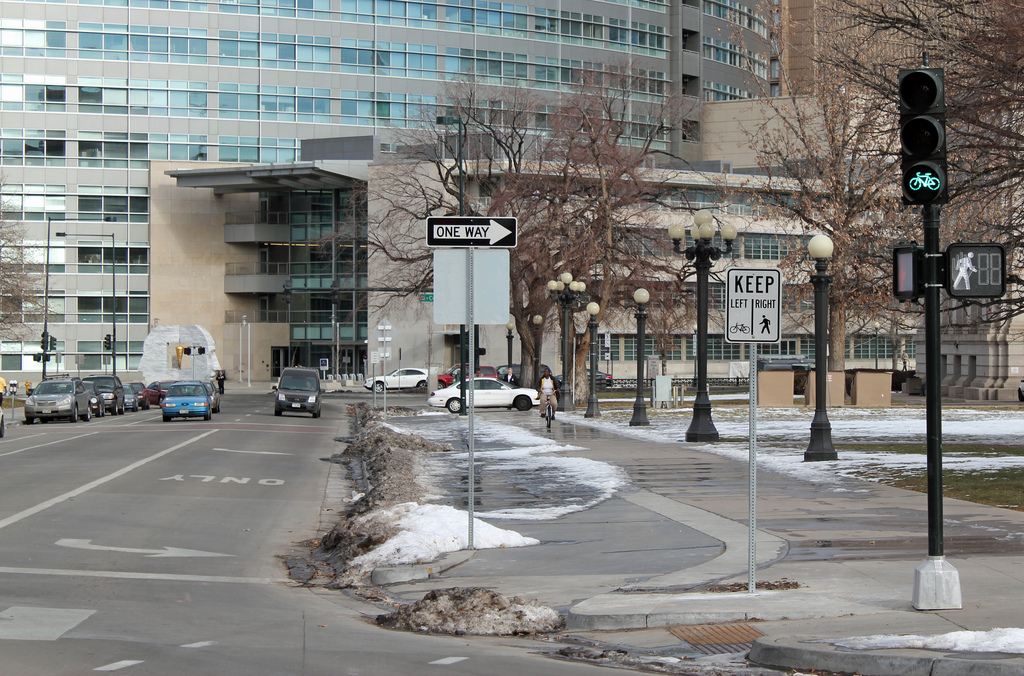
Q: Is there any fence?
A: No, there are no fences.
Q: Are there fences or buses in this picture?
A: No, there are no fences or buses.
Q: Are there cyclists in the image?
A: Yes, there is a cyclist.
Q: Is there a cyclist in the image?
A: Yes, there is a cyclist.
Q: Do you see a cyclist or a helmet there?
A: Yes, there is a cyclist.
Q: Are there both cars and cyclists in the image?
A: Yes, there are both a cyclist and a car.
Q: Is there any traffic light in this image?
A: Yes, there is a traffic light.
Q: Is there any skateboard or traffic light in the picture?
A: Yes, there is a traffic light.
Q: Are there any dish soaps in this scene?
A: No, there are no dish soaps.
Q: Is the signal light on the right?
A: Yes, the signal light is on the right of the image.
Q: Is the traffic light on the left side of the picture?
A: No, the traffic light is on the right of the image.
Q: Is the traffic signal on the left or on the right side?
A: The traffic signal is on the right of the image.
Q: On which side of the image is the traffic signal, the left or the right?
A: The traffic signal is on the right of the image.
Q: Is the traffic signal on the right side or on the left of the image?
A: The traffic signal is on the right of the image.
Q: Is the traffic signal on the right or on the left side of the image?
A: The traffic signal is on the right of the image.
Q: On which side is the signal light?
A: The signal light is on the right of the image.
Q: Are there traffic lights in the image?
A: Yes, there is a traffic light.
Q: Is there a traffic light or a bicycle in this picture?
A: Yes, there is a traffic light.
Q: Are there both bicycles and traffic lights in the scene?
A: Yes, there are both a traffic light and a bicycle.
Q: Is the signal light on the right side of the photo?
A: Yes, the signal light is on the right of the image.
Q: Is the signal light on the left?
A: No, the signal light is on the right of the image.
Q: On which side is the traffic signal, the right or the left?
A: The traffic signal is on the right of the image.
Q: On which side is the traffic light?
A: The traffic light is on the right of the image.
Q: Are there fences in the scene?
A: No, there are no fences.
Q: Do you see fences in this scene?
A: No, there are no fences.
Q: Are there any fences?
A: No, there are no fences.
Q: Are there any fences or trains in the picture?
A: No, there are no fences or trains.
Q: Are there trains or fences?
A: No, there are no fences or trains.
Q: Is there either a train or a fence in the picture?
A: No, there are no fences or trains.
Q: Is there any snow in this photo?
A: Yes, there is snow.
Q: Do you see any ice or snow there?
A: Yes, there is snow.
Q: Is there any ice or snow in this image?
A: Yes, there is snow.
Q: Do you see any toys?
A: No, there are no toys.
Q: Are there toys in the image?
A: No, there are no toys.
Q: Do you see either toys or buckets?
A: No, there are no toys or buckets.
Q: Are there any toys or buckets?
A: No, there are no toys or buckets.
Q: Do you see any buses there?
A: No, there are no buses.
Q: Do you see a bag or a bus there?
A: No, there are no buses or bags.